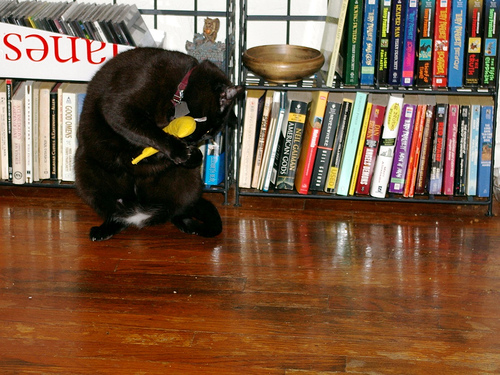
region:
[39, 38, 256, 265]
Black and white cat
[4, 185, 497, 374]
Beautiful dark wooden floor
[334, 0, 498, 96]
10 books on top shelf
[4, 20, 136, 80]
Red lettering on upside down white sign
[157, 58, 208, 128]
Red collar on cat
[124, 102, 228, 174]
Cat playing with yellow toy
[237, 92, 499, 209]
Whole row of books on bottom shelf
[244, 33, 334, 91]
Small brown dish for decoration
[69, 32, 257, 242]
Cat standing up and playing with toy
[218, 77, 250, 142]
Two black cat ears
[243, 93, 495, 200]
row of several paperback books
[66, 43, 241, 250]
black cat with red collar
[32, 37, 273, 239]
cat in front of several books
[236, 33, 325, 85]
wooden bowl on wire shelf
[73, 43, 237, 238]
cat gripping yellow banana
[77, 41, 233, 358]
cat on shiny hardwood floor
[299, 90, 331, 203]
red and yellow book spine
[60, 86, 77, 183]
white edge of Good Omens book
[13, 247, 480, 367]
section of brown hardwood floor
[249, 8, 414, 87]
little round bowl next to books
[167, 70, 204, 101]
Cat is wearing red collar.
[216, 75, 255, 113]
Cat has black ear.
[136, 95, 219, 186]
Cat is holding banana.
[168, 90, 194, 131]
Tags hanging from cat's collar.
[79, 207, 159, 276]
Cat has black paw.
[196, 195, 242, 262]
Cat has black tail.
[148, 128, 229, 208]
Cat has black paw.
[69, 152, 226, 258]
Cat is standing on back two legs.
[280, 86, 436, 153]
Many books on shelf.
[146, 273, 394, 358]
Brown hard wood floor.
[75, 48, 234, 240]
black house cat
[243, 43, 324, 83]
wooden bowl on the shelf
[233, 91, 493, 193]
shelf full of books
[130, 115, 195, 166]
yellow banana cat toy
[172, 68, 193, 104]
red collar on the cat's neck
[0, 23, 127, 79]
white sign with red writing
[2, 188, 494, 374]
shiny wood flooring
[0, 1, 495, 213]
metal shelves are full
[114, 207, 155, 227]
white patch on cat's fur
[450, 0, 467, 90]
blue book spine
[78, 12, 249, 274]
black dog holds toy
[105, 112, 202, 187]
toy is yellow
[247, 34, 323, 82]
brown bowl is behind dog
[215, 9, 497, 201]
numerous books on shelves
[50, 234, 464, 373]
floor is brown and shiny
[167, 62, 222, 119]
dog has red collar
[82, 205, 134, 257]
dog has black feet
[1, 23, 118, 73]
white box behind dog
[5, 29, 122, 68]
red letters on box